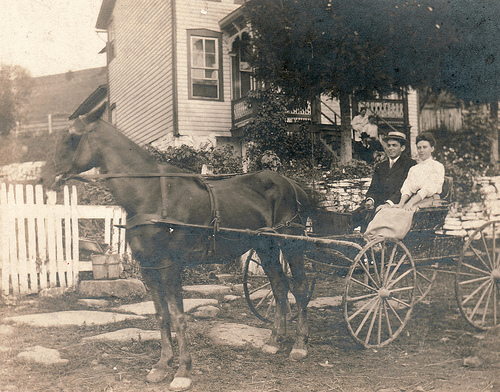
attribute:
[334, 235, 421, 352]
wheel — front tire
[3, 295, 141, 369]
rocks — large, flat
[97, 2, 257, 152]
house — wooden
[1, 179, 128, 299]
fence — white, picket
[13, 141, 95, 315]
fence — white